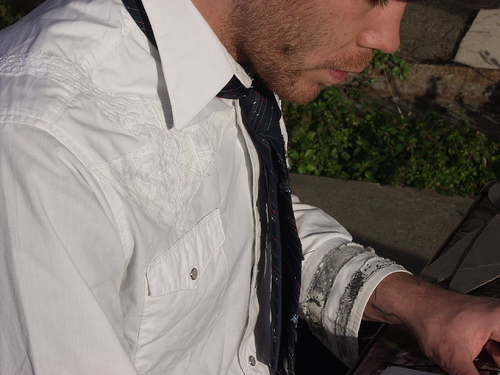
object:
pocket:
[133, 207, 232, 374]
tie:
[217, 78, 309, 374]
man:
[0, 0, 499, 374]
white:
[2, 137, 249, 373]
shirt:
[0, 0, 414, 374]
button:
[188, 267, 199, 280]